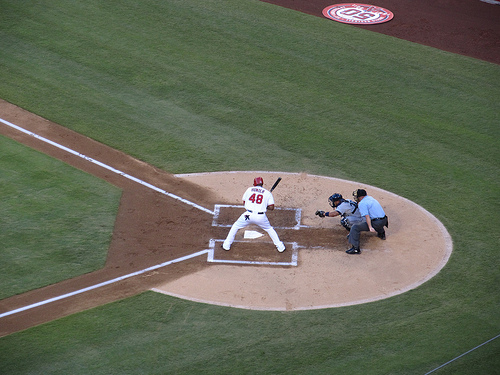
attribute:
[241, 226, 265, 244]
home plate — white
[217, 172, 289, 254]
baseball player — batting, ready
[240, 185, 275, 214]
shirt — baseball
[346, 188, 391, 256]
umpire — baseball, watching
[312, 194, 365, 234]
catcher — squating, baseball, ready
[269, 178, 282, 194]
bat — black, dark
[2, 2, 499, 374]
baseball field — green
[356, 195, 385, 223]
shirt — blue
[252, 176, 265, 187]
helmet — red, bright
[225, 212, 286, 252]
pants — white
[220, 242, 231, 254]
shoe — batter's, right shoe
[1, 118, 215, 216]
line — white, bright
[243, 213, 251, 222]
glove — black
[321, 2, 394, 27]
object — round